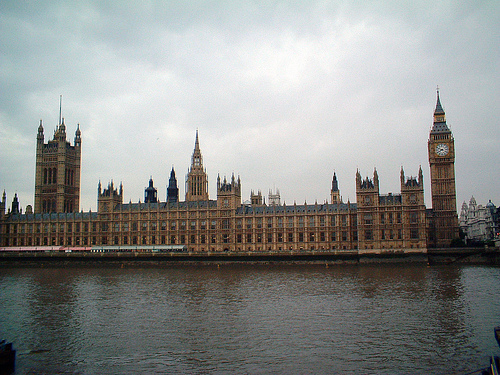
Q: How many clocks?
A: One.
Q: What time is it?
A: 9:40.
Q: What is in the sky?
A: Clouds.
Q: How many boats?
A: None.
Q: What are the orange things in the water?
A: Buoys.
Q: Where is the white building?
A: On the right.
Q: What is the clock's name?
A: Big Ben.